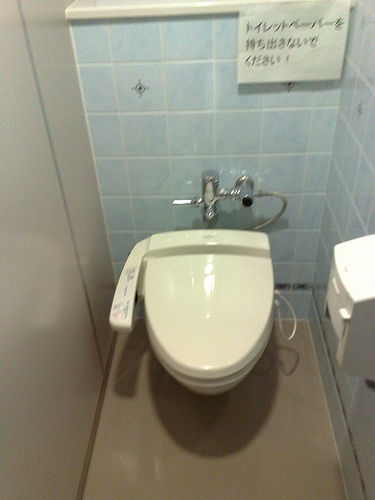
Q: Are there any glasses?
A: No, there are no glasses.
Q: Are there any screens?
A: No, there are no screens.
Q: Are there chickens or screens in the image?
A: No, there are no screens or chickens.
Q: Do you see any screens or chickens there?
A: No, there are no screens or chickens.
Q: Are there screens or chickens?
A: No, there are no screens or chickens.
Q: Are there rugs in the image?
A: No, there are no rugs.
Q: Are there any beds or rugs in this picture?
A: No, there are no rugs or beds.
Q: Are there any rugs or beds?
A: No, there are no rugs or beds.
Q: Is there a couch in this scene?
A: No, there are no couches.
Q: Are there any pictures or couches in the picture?
A: No, there are no couches or pictures.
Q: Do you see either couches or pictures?
A: No, there are no couches or pictures.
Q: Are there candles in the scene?
A: No, there are no candles.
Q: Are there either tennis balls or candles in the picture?
A: No, there are no candles or tennis balls.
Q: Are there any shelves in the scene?
A: No, there are no shelves.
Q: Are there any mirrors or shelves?
A: No, there are no shelves or mirrors.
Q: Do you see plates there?
A: No, there are no plates.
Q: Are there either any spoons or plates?
A: No, there are no plates or spoons.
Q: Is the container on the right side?
A: Yes, the container is on the right of the image.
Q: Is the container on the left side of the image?
A: No, the container is on the right of the image.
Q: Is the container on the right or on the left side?
A: The container is on the right of the image.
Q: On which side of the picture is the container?
A: The container is on the right of the image.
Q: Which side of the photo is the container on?
A: The container is on the right of the image.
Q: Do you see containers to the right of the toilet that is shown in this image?
A: Yes, there is a container to the right of the toilet.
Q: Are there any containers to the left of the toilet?
A: No, the container is to the right of the toilet.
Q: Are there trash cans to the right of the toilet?
A: No, there is a container to the right of the toilet.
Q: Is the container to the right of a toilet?
A: Yes, the container is to the right of a toilet.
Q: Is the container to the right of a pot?
A: No, the container is to the right of a toilet.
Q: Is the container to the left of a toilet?
A: No, the container is to the right of a toilet.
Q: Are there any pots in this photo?
A: No, there are no pots.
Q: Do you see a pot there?
A: No, there are no pots.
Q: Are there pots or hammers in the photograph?
A: No, there are no pots or hammers.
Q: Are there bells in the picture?
A: No, there are no bells.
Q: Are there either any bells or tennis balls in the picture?
A: No, there are no bells or tennis balls.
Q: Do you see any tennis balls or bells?
A: No, there are no bells or tennis balls.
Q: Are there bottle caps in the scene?
A: No, there are no bottle caps.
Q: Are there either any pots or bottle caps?
A: No, there are no bottle caps or pots.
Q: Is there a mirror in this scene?
A: No, there are no mirrors.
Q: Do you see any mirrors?
A: No, there are no mirrors.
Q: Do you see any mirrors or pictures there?
A: No, there are no mirrors or pictures.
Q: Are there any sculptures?
A: No, there are no sculptures.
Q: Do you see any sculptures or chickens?
A: No, there are no sculptures or chickens.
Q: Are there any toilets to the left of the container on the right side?
A: Yes, there is a toilet to the left of the container.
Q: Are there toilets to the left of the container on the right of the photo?
A: Yes, there is a toilet to the left of the container.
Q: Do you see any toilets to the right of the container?
A: No, the toilet is to the left of the container.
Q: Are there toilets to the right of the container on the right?
A: No, the toilet is to the left of the container.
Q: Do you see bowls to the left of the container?
A: No, there is a toilet to the left of the container.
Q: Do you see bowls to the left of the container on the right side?
A: No, there is a toilet to the left of the container.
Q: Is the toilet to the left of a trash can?
A: No, the toilet is to the left of the container.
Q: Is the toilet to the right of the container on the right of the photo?
A: No, the toilet is to the left of the container.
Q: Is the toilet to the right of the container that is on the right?
A: No, the toilet is to the left of the container.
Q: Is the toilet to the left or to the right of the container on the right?
A: The toilet is to the left of the container.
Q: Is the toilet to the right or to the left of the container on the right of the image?
A: The toilet is to the left of the container.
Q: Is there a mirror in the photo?
A: No, there are no mirrors.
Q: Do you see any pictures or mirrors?
A: No, there are no mirrors or pictures.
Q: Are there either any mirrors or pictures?
A: No, there are no mirrors or pictures.